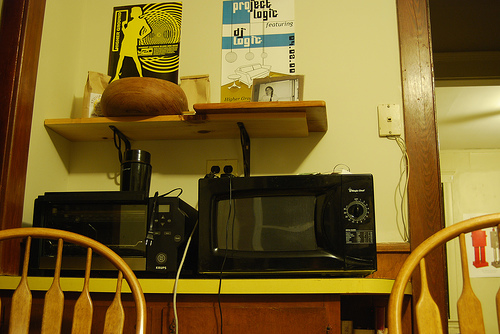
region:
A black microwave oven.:
[183, 165, 384, 292]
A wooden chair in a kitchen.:
[0, 210, 167, 327]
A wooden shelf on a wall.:
[39, 90, 337, 176]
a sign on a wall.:
[209, 0, 305, 118]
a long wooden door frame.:
[390, 0, 457, 332]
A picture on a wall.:
[109, 0, 189, 87]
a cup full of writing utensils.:
[104, 129, 163, 204]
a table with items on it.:
[1, 263, 423, 314]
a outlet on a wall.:
[371, 105, 411, 137]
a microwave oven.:
[21, 145, 207, 277]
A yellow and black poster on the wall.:
[108, 3, 181, 80]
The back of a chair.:
[0, 228, 147, 332]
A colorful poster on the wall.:
[221, 0, 299, 97]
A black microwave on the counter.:
[197, 174, 376, 275]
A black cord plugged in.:
[212, 159, 235, 332]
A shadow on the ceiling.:
[438, 100, 498, 132]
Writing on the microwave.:
[343, 225, 374, 247]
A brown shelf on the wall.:
[42, 98, 328, 174]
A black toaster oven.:
[24, 190, 192, 277]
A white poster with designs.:
[460, 214, 499, 276]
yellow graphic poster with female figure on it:
[109, 4, 183, 83]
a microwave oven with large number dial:
[197, 169, 379, 281]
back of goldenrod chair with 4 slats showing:
[0, 223, 152, 333]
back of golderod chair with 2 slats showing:
[382, 211, 499, 333]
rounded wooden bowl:
[100, 75, 189, 116]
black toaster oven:
[27, 190, 197, 277]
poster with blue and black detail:
[217, 3, 303, 98]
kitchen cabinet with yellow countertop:
[3, 277, 414, 331]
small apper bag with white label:
[79, 69, 111, 118]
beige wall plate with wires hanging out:
[373, 96, 405, 246]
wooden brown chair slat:
[68, 245, 96, 332]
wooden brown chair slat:
[103, 269, 127, 332]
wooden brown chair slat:
[41, 235, 65, 332]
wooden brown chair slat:
[9, 236, 31, 331]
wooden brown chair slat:
[414, 256, 443, 332]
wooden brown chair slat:
[457, 230, 487, 331]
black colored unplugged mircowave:
[198, 175, 379, 274]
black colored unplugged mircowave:
[28, 189, 179, 274]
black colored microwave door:
[197, 178, 344, 271]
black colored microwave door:
[38, 197, 145, 272]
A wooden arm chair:
[2, 232, 136, 332]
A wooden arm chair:
[384, 230, 497, 329]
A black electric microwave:
[41, 188, 191, 288]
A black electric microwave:
[188, 174, 383, 282]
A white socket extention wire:
[390, 137, 416, 242]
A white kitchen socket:
[202, 159, 241, 179]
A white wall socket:
[379, 104, 402, 139]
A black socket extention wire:
[209, 168, 261, 322]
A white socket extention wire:
[163, 250, 189, 332]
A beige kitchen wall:
[331, 111, 378, 155]